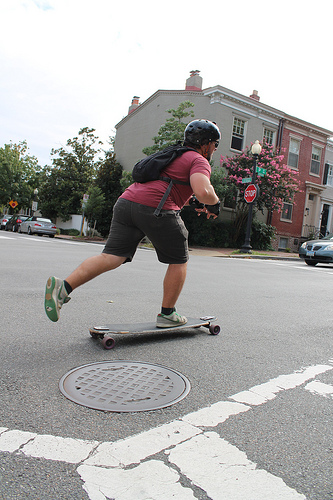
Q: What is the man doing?
A: Skateboarding.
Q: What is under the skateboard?
A: The road.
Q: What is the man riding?
A: A skateboard.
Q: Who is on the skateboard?
A: The man.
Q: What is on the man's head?
A: A helmet.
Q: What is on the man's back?
A: A backpack.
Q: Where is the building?
A: Across the road.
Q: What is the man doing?
A: Skateboarding.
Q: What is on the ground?
A: A manhole cover.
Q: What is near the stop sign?
A: A tree with pink flowers.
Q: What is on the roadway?
A: White lines.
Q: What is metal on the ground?
A: A manhole cover.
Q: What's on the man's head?
A: A helmet.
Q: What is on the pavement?
A: White markings.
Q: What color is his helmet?
A: Black.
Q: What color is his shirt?
A: Red.